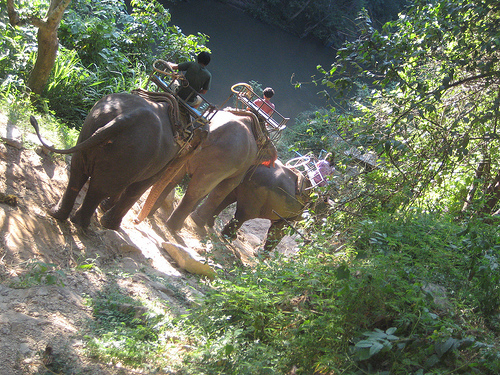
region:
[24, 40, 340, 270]
three elephants carrying passengers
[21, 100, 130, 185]
elephant's tail is swinging up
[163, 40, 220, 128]
a man is sitting on the elephant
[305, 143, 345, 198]
a person is riding on an elephant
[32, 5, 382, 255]
the elephants are going into the river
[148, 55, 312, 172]
a round ring is attached to each trekking chair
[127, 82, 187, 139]
blankets are under the elephant trekking chair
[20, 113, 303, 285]
the dirt trail leads into the river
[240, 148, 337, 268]
the elephant is entering the water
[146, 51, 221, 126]
a man is in an elephant trekking chair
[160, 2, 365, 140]
the water is blue.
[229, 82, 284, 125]
person riding an elephant.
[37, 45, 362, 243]
the elephants are carrying people.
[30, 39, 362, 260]
elephants standing on the dirt.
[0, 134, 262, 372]
the dirt is brown.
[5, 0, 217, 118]
the leaves are green.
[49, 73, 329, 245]
three elephants are walking.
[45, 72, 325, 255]
the elephants are brown.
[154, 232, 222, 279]
rock on the ground.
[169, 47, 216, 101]
person's shirt is green.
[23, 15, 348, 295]
people riding elephants in the woods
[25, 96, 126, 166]
tail of an elephant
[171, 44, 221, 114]
person riding an elephant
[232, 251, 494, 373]
green leaves on trees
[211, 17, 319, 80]
water of a river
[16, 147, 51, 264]
dirt ground where elephants are walking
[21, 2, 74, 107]
trunk of a tree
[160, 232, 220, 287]
pillow on the ground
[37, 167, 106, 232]
back legs of an elephant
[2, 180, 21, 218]
feces of an elephant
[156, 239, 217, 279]
grey rock on side of road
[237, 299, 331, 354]
green bushes on side of road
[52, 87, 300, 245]
three elephants in a row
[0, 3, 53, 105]
tree trunk standing up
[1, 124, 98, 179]
elephant swinging tail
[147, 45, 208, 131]
person on back of elephant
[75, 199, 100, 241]
right back elephant foot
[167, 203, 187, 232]
right back elephant foot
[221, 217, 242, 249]
right back elephant foot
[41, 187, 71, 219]
left back elephant foot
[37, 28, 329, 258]
people riding elephants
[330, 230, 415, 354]
a thicket of green bushes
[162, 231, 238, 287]
a large white stone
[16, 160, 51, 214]
a dirt path in the woods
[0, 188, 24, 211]
a pile of elephant dung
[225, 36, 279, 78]
a black river at the end of the path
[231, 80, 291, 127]
a wooden riding bench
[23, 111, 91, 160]
the gray tail of an elephant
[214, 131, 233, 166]
gray wrinkled skin on an elephant back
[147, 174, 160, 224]
the rough gray trunk of an elephant